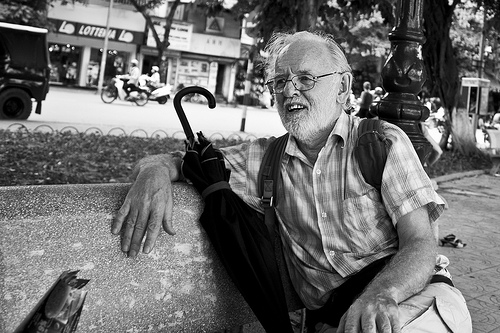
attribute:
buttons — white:
[314, 164, 336, 264]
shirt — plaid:
[203, 117, 451, 289]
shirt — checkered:
[216, 107, 442, 316]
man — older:
[86, 16, 444, 330]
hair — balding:
[272, 32, 353, 98]